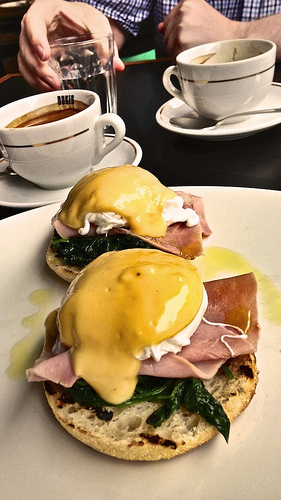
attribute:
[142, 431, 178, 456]
part — burnt